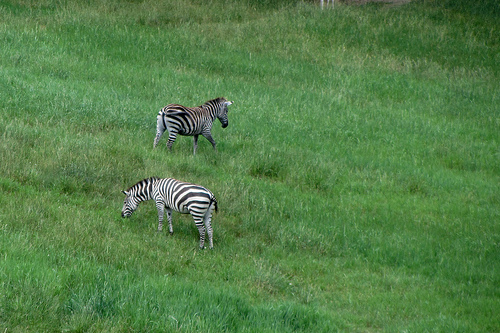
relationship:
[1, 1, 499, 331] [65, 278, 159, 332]
field of grass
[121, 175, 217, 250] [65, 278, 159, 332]
zebra feeding on grass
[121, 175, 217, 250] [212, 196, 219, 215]
zebra has tail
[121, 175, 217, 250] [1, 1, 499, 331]
zebra in field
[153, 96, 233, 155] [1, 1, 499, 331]
zebra in field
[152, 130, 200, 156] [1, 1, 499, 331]
legs touching field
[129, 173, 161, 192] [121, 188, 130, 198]
mane and ears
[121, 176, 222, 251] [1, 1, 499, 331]
zebra in field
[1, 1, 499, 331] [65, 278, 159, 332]
field covered in grass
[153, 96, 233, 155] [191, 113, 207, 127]
zebra has pattern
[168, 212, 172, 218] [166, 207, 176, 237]
spot on leg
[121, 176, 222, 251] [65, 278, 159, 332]
zebra in grass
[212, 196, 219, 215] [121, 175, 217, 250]
tail of zebra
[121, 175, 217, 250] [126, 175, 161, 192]
zebra has mane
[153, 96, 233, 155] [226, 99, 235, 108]
zebra has ear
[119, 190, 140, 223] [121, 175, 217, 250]
head of zebra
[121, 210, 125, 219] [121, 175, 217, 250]
nose of zebra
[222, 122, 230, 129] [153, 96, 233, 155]
nose of zebra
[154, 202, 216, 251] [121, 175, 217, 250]
legs of zebra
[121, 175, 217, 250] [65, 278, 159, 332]
zebra in grass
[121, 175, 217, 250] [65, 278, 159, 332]
zebra eating grass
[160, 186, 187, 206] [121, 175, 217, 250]
stripes on zebra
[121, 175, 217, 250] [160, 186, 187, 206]
zebra has stripes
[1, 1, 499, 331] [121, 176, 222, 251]
field with zebra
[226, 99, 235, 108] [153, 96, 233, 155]
ear of zebra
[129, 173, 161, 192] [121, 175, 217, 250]
mane of zebra